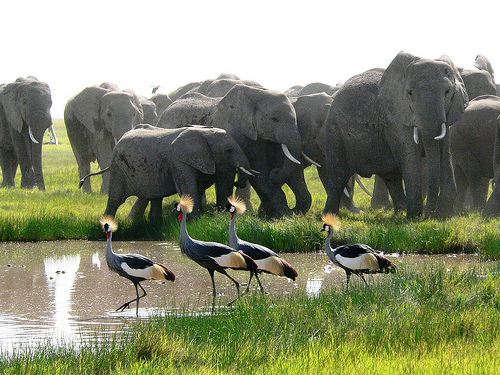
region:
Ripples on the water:
[10, 310, 82, 332]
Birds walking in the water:
[90, 189, 393, 302]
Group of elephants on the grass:
[7, 61, 487, 238]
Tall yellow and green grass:
[262, 318, 469, 363]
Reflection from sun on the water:
[38, 248, 89, 341]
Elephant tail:
[72, 156, 110, 193]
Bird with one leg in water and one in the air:
[95, 206, 171, 342]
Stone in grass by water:
[129, 337, 167, 367]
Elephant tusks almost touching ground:
[340, 171, 380, 211]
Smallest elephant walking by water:
[108, 118, 254, 245]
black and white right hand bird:
[313, 208, 410, 293]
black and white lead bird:
[87, 203, 180, 335]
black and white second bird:
[167, 190, 262, 322]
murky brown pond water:
[5, 230, 462, 351]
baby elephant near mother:
[77, 117, 262, 227]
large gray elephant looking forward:
[312, 47, 472, 238]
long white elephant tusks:
[273, 140, 325, 172]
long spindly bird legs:
[110, 275, 157, 324]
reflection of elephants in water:
[1, 243, 154, 345]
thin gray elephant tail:
[72, 156, 115, 201]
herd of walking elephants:
[106, 53, 468, 223]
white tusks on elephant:
[275, 141, 315, 173]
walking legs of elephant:
[274, 173, 323, 219]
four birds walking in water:
[90, 196, 372, 308]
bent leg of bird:
[113, 277, 157, 321]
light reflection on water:
[33, 246, 89, 319]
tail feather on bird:
[277, 259, 307, 291]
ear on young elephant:
[169, 123, 222, 177]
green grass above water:
[25, 210, 82, 249]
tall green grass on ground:
[410, 264, 473, 322]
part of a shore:
[263, 297, 313, 344]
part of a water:
[82, 277, 111, 312]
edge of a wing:
[206, 240, 241, 272]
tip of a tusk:
[279, 135, 300, 167]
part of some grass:
[275, 295, 333, 358]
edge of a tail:
[232, 242, 259, 274]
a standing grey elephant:
[74, 125, 259, 221]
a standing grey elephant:
[0, 75, 60, 192]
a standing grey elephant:
[63, 85, 158, 188]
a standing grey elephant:
[159, 85, 321, 219]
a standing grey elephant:
[324, 51, 466, 218]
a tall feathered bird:
[317, 211, 401, 293]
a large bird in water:
[218, 193, 300, 309]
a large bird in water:
[166, 194, 258, 312]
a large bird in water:
[96, 214, 175, 319]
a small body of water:
[0, 244, 493, 354]